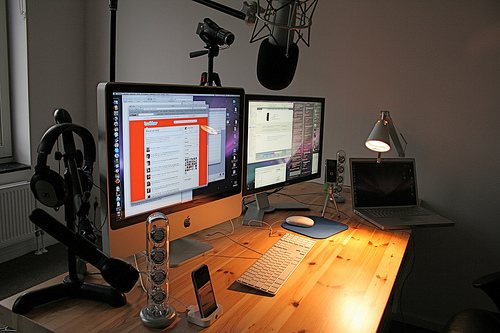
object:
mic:
[27, 209, 140, 295]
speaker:
[330, 147, 348, 204]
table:
[0, 180, 411, 333]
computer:
[97, 81, 245, 267]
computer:
[245, 93, 326, 226]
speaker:
[140, 212, 176, 327]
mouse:
[285, 215, 315, 228]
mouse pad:
[280, 215, 349, 239]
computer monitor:
[241, 93, 326, 225]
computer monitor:
[96, 79, 247, 268]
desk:
[0, 180, 408, 333]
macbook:
[349, 157, 456, 231]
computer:
[95, 81, 325, 267]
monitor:
[244, 95, 325, 199]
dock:
[183, 307, 223, 329]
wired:
[207, 219, 289, 256]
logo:
[183, 215, 191, 228]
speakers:
[140, 149, 348, 329]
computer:
[94, 81, 326, 260]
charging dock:
[185, 303, 223, 327]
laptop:
[347, 156, 451, 231]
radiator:
[0, 179, 48, 256]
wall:
[1, 0, 92, 258]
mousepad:
[281, 215, 349, 239]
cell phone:
[190, 263, 217, 316]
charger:
[187, 302, 223, 327]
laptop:
[348, 156, 455, 231]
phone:
[189, 263, 217, 317]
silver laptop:
[348, 157, 457, 232]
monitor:
[95, 80, 243, 257]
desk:
[0, 182, 413, 333]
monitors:
[94, 80, 327, 258]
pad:
[281, 215, 350, 240]